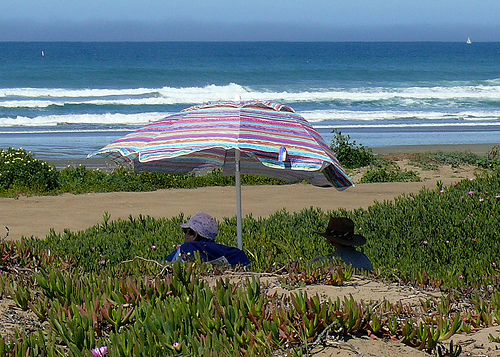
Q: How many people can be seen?
A: Two.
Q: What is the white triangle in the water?
A: Boat sail.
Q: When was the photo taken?
A: Daytime.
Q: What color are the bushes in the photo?
A: Green.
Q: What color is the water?
A: Blue.